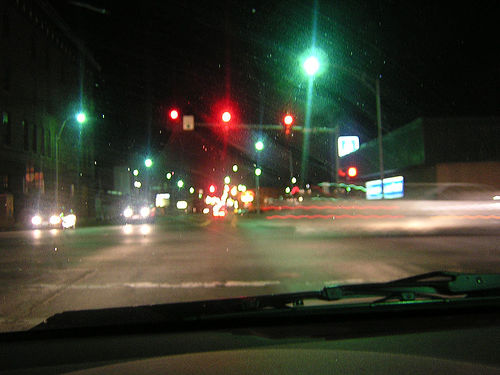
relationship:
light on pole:
[297, 49, 326, 79] [330, 63, 386, 200]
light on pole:
[70, 110, 92, 128] [54, 114, 76, 215]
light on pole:
[211, 100, 242, 131] [194, 122, 339, 183]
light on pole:
[167, 108, 180, 121] [194, 122, 339, 183]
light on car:
[141, 207, 152, 217] [124, 198, 156, 223]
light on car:
[50, 215, 60, 225] [32, 206, 77, 228]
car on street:
[124, 198, 156, 223] [0, 212, 499, 332]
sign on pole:
[183, 116, 195, 131] [194, 122, 339, 183]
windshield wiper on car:
[29, 269, 500, 330] [1, 269, 498, 374]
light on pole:
[283, 114, 295, 126] [194, 122, 339, 183]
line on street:
[18, 280, 369, 288] [0, 212, 499, 332]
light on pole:
[255, 140, 265, 151] [264, 140, 295, 189]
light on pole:
[255, 167, 262, 176] [238, 165, 260, 216]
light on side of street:
[255, 140, 265, 151] [0, 212, 499, 332]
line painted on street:
[18, 280, 369, 288] [0, 212, 499, 332]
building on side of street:
[338, 116, 499, 196] [0, 212, 499, 332]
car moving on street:
[1, 269, 498, 374] [0, 212, 499, 332]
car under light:
[32, 206, 77, 228] [70, 110, 92, 128]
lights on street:
[203, 176, 254, 216] [0, 212, 499, 332]